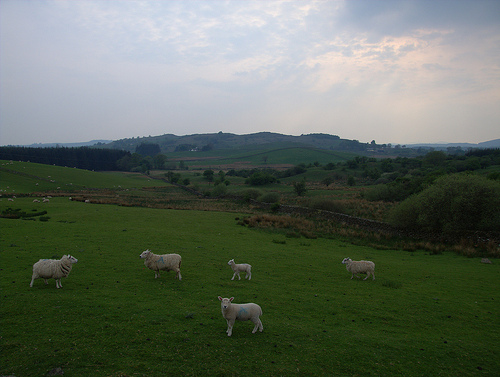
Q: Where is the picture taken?
A: In a field.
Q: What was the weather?
A: Cloudy.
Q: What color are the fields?
A: Green.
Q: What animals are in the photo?
A: Sheep.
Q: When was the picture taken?
A: Daytime.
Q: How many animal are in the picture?
A: Five in the foreground.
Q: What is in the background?
A: Rolling hills.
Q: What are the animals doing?
A: Standing in the field.